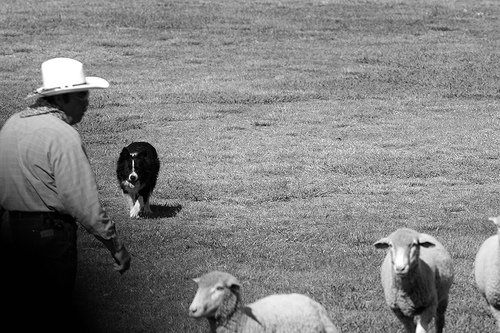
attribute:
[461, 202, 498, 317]
sheep — white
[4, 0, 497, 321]
field — grassy 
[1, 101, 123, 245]
shirt — long sleeved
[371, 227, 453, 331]
sheep — walking, white 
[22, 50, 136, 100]
hat — white 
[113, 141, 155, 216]
dog — black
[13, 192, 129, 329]
pants — black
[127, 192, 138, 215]
leg — white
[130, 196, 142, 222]
leg — white